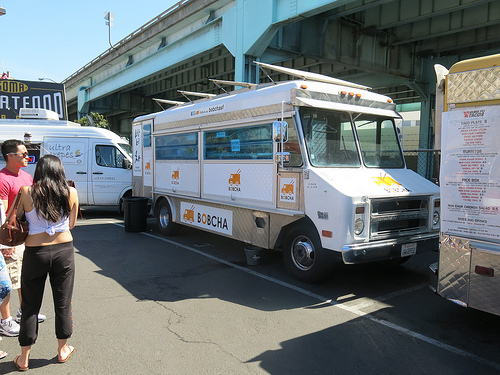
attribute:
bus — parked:
[133, 58, 439, 280]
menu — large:
[441, 107, 497, 243]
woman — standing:
[13, 153, 74, 374]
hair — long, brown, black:
[35, 155, 71, 221]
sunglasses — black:
[6, 152, 28, 160]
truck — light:
[131, 59, 440, 282]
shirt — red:
[1, 168, 32, 217]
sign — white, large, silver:
[439, 103, 498, 243]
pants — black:
[19, 240, 74, 344]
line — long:
[113, 219, 498, 373]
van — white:
[2, 106, 135, 215]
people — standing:
[1, 140, 80, 372]